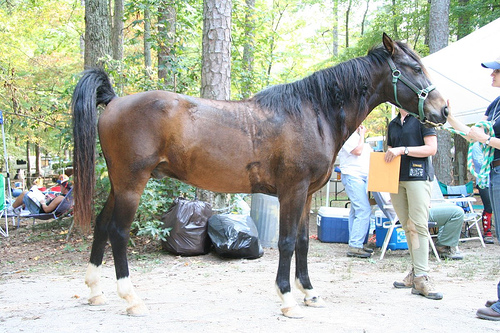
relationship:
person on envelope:
[390, 107, 437, 297] [365, 149, 400, 195]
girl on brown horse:
[438, 57, 499, 322] [69, 32, 449, 319]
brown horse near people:
[69, 32, 449, 319] [6, 178, 71, 218]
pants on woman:
[389, 181, 431, 281] [382, 102, 442, 301]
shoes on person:
[393, 270, 443, 305] [377, 106, 445, 303]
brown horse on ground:
[69, 32, 449, 319] [173, 273, 242, 323]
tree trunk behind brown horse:
[200, 0, 236, 102] [69, 32, 449, 319]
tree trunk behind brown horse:
[83, 0, 110, 76] [69, 32, 449, 319]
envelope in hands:
[366, 152, 400, 193] [383, 147, 399, 161]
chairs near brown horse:
[370, 179, 491, 274] [69, 32, 449, 319]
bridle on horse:
[381, 52, 459, 124] [80, 41, 459, 286]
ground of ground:
[0, 178, 500, 333] [3, 252, 495, 329]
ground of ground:
[0, 178, 500, 333] [204, 252, 233, 287]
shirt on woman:
[382, 113, 437, 183] [382, 105, 459, 307]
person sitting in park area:
[426, 192, 465, 259] [12, 137, 188, 269]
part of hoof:
[264, 294, 302, 318] [281, 304, 307, 319]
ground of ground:
[0, 178, 500, 333] [0, 178, 500, 331]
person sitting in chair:
[0, 165, 82, 231] [20, 184, 91, 248]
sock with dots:
[467, 207, 484, 240] [480, 212, 484, 231]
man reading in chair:
[427, 191, 466, 258] [358, 124, 498, 251]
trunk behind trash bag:
[177, 16, 258, 103] [208, 208, 263, 258]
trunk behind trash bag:
[177, 16, 258, 103] [160, 198, 212, 255]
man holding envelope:
[366, 101, 440, 305] [369, 150, 401, 190]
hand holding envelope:
[382, 144, 402, 161] [369, 150, 401, 190]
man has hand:
[366, 101, 440, 305] [382, 144, 402, 161]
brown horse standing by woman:
[72, 58, 402, 283] [385, 87, 472, 309]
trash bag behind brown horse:
[208, 210, 266, 256] [69, 32, 449, 319]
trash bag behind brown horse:
[160, 198, 212, 255] [69, 32, 449, 319]